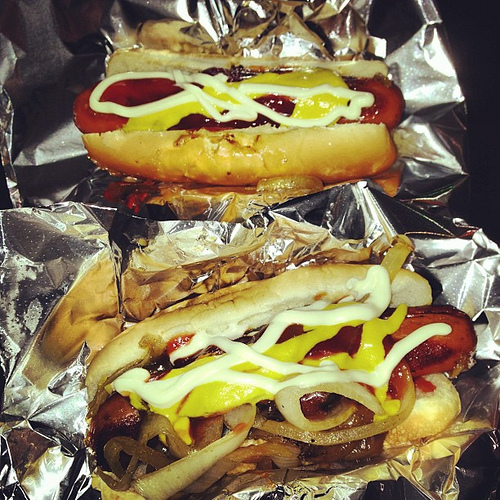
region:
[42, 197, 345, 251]
aluminum foil used as heat insulator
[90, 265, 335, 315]
bread used for hotdog bun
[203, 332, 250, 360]
mayonnaise used on hotdog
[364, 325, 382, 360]
mustard used on hotdog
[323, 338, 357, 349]
ketchup used on hotdog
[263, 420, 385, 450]
sliver of onions used on hotdog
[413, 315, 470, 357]
Weiner used as meat on hotdog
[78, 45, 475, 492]
two hotdogs in aluminum foil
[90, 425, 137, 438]
dark sauce on hotdog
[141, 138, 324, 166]
greasy spots on bread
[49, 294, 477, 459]
Hot dog on tin foil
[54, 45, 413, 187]
Hot dog on tin foil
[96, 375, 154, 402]
Sauce on hot dog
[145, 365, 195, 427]
Sauce on hot dog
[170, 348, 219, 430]
Sauce on hot dog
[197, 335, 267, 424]
Sauce on hot dog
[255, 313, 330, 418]
Sauce on hot dog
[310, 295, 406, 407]
Sauce on hot dog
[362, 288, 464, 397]
Sauce on hot dog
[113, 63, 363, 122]
Sauce on hot dog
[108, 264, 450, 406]
mayonnaise on a hotdog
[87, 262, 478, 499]
hotdog on a bun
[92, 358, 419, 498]
cooked onions on a hotdog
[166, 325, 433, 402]
ketchup on a hotdog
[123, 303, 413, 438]
mustard on a hotdog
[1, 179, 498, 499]
aluminum foil holder for hotdog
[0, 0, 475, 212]
aluminum foil holder for hotdog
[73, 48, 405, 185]
hotdog on a bun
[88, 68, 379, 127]
mayonnaise on a hotdog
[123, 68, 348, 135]
mustard on a hotdog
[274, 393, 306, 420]
the onions are clear white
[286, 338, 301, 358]
the mustard is yellow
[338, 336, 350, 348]
the ketchup is red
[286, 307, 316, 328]
the mayo is white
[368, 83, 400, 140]
the hot dog is on the bun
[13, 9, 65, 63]
the aluminum foil is silver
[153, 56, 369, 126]
the hot dog has no onions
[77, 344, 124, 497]
the bun is on the foil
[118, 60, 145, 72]
the hot dog bun is white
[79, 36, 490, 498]
two hot dogs on buns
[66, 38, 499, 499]
hot dogs on tin foil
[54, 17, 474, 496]
hot dogs on aluminum foil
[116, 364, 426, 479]
onions on a hot dog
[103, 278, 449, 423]
mustard and mayo on a hot dog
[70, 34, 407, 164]
a hot dog with toppings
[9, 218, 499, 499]
a hot dog with lots of toppings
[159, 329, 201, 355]
a spot of ketchup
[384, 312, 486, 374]
a grilled hotdog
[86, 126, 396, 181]
the top of a hot dog bun